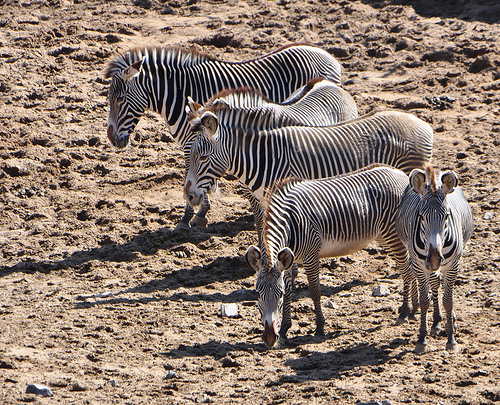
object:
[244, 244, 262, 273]
ear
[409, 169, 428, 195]
ear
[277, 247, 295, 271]
ear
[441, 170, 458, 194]
ear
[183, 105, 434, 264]
zebra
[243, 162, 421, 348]
zebra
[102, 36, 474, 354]
group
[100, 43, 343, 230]
zebra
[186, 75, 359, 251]
zebra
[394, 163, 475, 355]
zebra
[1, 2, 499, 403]
bare ground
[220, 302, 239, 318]
rock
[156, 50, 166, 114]
stripes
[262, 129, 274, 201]
stripes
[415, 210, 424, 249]
stripes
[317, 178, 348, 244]
stripes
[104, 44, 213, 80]
mane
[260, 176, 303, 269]
mane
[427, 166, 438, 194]
mane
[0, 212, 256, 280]
shadow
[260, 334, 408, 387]
shadow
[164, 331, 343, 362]
shadow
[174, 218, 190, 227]
hooves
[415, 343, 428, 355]
hooves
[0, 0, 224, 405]
sideways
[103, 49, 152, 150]
head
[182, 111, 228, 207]
head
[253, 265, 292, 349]
head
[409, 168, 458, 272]
head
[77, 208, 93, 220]
dirt clumps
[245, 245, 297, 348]
zebra head